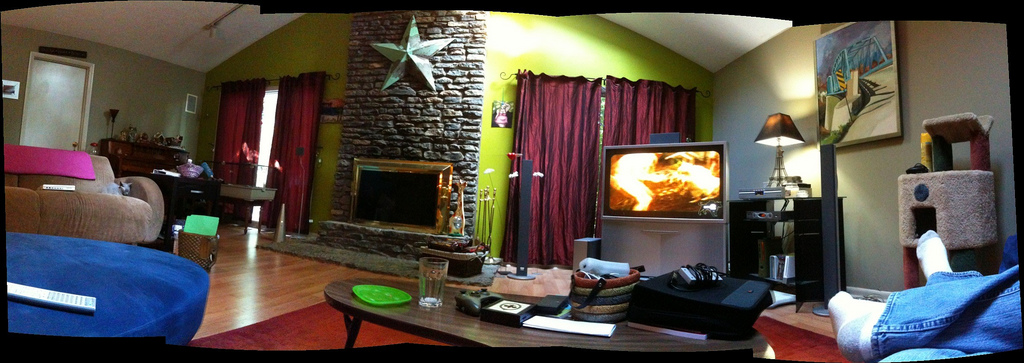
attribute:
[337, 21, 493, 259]
fireplace — brick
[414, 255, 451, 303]
glass — clear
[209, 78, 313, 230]
curtain — red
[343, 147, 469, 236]
fireplace — brass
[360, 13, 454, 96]
bronze star — large, on the fireplace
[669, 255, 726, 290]
grey/black controller — on a coffee table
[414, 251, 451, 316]
clear glass — on a table top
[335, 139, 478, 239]
place — fire 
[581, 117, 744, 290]
television — grey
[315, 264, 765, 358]
coffee table — brown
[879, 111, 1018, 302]
cat house — multi-storied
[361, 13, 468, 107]
star — large, silver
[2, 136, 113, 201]
blanket — pink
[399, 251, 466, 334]
glass — empty